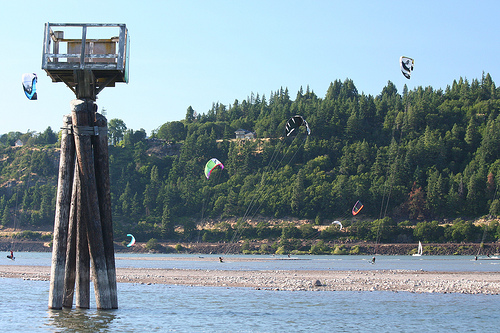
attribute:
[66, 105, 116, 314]
log — large, brown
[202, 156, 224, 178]
kite — green, pink, water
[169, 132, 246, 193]
kite — green, pink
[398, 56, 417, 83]
kite — water, black, white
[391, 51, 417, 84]
kite — white, black, blue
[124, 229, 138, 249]
parasail — low flying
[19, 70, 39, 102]
kite — water, white, blue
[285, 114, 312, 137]
kite — water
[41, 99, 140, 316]
poles — support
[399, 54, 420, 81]
kite — white, black, water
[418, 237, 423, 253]
sail — white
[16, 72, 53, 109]
parasail — blue, black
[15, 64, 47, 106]
kite — blue, black